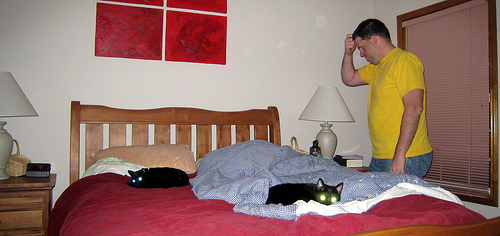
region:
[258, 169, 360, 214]
cat with glowing eyes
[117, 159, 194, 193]
cat with glowing eyes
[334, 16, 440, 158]
man wearing yellow shirt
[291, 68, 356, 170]
white lamp on night table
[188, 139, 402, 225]
cat laying on purple blanket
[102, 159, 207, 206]
cat laying on red blanket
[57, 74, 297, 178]
brown wooden headboard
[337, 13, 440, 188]
man wearing blue jeans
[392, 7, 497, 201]
windows with blinds rolled down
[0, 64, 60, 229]
white lamp on brown night table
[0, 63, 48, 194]
white lamp on nightstand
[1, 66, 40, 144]
white shade on lamp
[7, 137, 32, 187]
small wicker basket on nightstand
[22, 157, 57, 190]
digital alarm clock on nightstand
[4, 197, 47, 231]
drawer in nightstand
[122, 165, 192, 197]
black cat on red bedspread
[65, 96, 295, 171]
wooden headboard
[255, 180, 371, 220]
black cat on blue blanket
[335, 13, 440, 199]
man in yellow t-shirt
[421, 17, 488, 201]
white mini blinds on window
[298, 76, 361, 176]
lamp on bedside table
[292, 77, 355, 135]
white lampshade on lamp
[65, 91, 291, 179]
slatted wooden headboard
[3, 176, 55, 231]
wooden bedside table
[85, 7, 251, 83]
red and white poster on the wall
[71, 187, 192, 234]
red bedspread on bed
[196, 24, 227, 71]
a red side of the painting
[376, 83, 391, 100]
the man's yellow shirt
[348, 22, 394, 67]
the man's head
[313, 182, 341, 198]
the black cat's creepy eyes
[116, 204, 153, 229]
the red blanket on the bed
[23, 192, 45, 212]
the brown wooden dresser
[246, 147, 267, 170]
the blue blanket on the bed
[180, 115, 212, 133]
the wooden head board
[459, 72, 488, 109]
these are the blinds in the house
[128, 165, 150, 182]
the other cat's eyes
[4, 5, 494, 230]
a bedroom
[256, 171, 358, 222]
black cat sleeping on a duvet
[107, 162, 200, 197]
black cat sleeping on a red blanket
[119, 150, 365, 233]
two car sleeping on a bed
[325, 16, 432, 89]
a man scratching his head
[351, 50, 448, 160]
man wearing a yellow shirt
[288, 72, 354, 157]
a white lamp on a night table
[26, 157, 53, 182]
an alarm clock on a night table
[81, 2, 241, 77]
an abstract painting on the wall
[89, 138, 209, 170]
a peach pillow on the bed